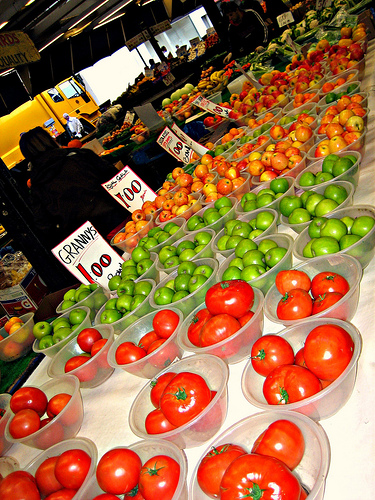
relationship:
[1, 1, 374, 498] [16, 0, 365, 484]
market has produce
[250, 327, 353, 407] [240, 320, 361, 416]
tomatoes in a basket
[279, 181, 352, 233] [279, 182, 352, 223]
bowl contains apples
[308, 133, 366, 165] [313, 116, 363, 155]
bowl contains apples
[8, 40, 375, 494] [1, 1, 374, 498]
table in market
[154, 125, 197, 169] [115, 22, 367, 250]
sign for apples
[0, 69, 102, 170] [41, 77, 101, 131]
truck has cab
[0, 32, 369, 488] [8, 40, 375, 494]
cloth covering table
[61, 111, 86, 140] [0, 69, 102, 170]
driver exiting truck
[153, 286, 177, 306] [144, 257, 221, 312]
apple in bowl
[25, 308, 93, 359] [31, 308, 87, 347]
bowl contains fruit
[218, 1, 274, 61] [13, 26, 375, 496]
person behind fruit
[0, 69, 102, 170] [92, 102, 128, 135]
truck behind person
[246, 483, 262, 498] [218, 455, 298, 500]
part of tomato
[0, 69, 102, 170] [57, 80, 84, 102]
truck has window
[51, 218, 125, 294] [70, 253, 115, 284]
sign says 1.00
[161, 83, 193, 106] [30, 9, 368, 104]
melon in background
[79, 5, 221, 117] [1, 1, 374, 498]
window at side of market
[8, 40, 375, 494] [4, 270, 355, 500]
table has fruit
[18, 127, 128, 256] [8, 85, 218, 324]
shopper in dark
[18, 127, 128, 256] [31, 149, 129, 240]
customer wearing black